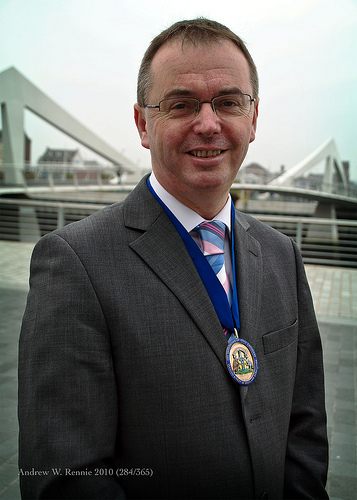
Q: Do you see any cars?
A: No, there are no cars.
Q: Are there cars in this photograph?
A: No, there are no cars.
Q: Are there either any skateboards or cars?
A: No, there are no cars or skateboards.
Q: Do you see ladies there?
A: No, there are no ladies.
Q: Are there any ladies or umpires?
A: No, there are no ladies or umpires.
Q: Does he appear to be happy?
A: Yes, the man is happy.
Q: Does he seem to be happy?
A: Yes, the man is happy.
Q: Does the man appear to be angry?
A: No, the man is happy.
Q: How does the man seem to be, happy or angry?
A: The man is happy.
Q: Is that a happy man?
A: Yes, that is a happy man.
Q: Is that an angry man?
A: No, that is a happy man.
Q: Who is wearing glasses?
A: The man is wearing glasses.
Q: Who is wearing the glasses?
A: The man is wearing glasses.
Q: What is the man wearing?
A: The man is wearing glasses.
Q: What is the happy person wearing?
A: The man is wearing glasses.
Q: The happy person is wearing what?
A: The man is wearing glasses.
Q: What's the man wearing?
A: The man is wearing glasses.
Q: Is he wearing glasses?
A: Yes, the man is wearing glasses.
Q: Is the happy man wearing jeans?
A: No, the man is wearing glasses.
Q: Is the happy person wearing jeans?
A: No, the man is wearing glasses.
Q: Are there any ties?
A: Yes, there is a tie.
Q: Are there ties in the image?
A: Yes, there is a tie.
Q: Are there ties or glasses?
A: Yes, there is a tie.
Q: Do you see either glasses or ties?
A: Yes, there is a tie.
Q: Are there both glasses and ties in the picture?
A: Yes, there are both a tie and glasses.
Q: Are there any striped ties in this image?
A: Yes, there is a striped tie.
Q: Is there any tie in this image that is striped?
A: Yes, there is a tie that is striped.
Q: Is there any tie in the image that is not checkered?
A: Yes, there is a striped tie.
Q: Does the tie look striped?
A: Yes, the tie is striped.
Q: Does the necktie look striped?
A: Yes, the necktie is striped.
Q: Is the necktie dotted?
A: No, the necktie is striped.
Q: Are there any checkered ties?
A: No, there is a tie but it is striped.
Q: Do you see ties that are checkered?
A: No, there is a tie but it is striped.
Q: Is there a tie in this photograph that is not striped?
A: No, there is a tie but it is striped.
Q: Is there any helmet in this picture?
A: No, there are no helmets.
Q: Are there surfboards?
A: No, there are no surfboards.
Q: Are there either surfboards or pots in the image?
A: No, there are no surfboards or pots.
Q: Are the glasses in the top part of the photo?
A: Yes, the glasses are in the top of the image.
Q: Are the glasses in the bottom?
A: No, the glasses are in the top of the image.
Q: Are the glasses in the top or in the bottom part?
A: The glasses are in the top of the image.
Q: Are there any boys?
A: No, there are no boys.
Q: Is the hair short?
A: Yes, the hair is short.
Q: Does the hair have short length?
A: Yes, the hair is short.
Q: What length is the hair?
A: The hair is short.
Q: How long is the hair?
A: The hair is short.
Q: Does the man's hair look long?
A: No, the hair is short.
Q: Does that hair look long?
A: No, the hair is short.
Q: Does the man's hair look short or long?
A: The hair is short.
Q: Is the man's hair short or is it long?
A: The hair is short.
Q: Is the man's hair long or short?
A: The hair is short.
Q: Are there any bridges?
A: Yes, there is a bridge.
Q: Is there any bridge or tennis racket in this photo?
A: Yes, there is a bridge.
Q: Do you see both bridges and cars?
A: No, there is a bridge but no cars.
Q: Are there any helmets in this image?
A: No, there are no helmets.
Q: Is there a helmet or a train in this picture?
A: No, there are no helmets or trains.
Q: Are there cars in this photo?
A: No, there are no cars.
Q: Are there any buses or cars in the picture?
A: No, there are no cars or buses.